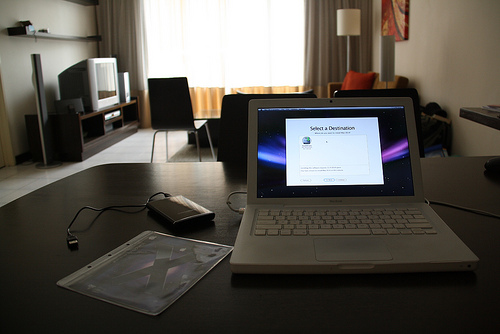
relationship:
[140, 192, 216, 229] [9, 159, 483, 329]
hard drive on desk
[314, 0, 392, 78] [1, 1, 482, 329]
lamp in corner of room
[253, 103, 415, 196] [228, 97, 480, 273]
screen on computer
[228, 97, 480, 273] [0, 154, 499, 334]
computer on desk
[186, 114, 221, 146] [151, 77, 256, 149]
table in middle of furniture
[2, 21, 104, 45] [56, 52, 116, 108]
shelf above television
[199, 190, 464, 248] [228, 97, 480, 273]
keyboard on a computer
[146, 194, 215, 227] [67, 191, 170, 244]
hard drive with cord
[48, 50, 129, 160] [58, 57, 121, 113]
entertainment center with television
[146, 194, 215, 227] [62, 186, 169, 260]
hard drive and cord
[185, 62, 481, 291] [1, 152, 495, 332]
computer sitting on a table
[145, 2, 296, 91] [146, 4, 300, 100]
light coming through curtains